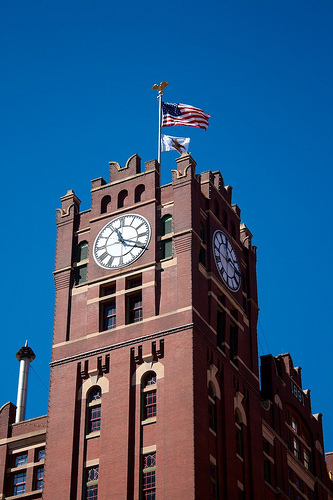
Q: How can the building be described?
A: A red brick building.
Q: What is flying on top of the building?
A: A flag.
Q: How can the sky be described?
A: Clear blue sky.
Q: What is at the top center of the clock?
A: A clock.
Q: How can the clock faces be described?
A: Black and white.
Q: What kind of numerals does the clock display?
A: Roman numerals.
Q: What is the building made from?
A: Bricks.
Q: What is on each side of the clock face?
A: An arched window.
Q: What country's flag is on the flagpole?
A: The United States.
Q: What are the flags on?
A: Pole.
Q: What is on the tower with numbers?
A: Clocks.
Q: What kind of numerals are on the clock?
A: Roman.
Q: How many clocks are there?
A: Two.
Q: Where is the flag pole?
A: Top of tower.